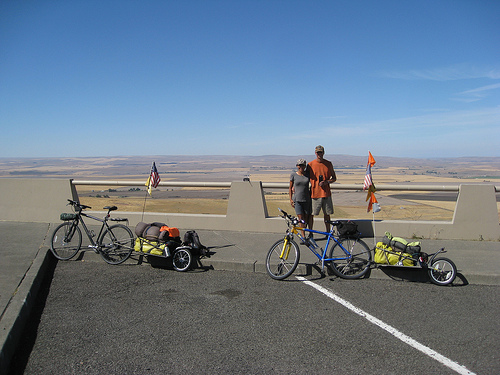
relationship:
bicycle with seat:
[54, 196, 136, 270] [99, 205, 123, 213]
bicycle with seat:
[264, 206, 372, 281] [322, 218, 347, 227]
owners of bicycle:
[286, 145, 337, 247] [47, 196, 136, 270]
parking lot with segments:
[0, 259, 500, 372] [40, 273, 496, 333]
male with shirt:
[306, 143, 337, 240] [304, 159, 339, 199]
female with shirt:
[286, 157, 318, 245] [286, 168, 316, 204]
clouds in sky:
[357, 109, 498, 156] [3, 1, 499, 158]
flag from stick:
[139, 161, 163, 219] [138, 194, 152, 223]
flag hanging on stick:
[139, 161, 163, 219] [138, 194, 152, 223]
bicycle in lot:
[47, 196, 136, 270] [0, 259, 500, 372]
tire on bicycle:
[52, 221, 85, 264] [47, 196, 136, 270]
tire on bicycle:
[99, 224, 138, 268] [47, 196, 136, 270]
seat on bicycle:
[99, 205, 123, 213] [47, 196, 136, 270]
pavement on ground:
[56, 258, 356, 374] [0, 259, 500, 372]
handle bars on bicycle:
[66, 196, 91, 214] [47, 196, 136, 270]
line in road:
[291, 274, 461, 374] [0, 259, 500, 372]